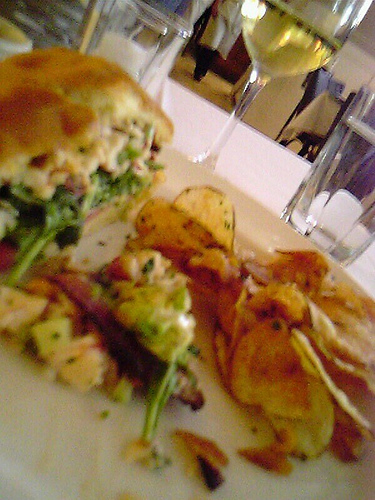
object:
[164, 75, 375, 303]
table cloth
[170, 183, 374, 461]
chips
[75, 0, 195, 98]
glass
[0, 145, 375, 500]
plate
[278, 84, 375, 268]
glass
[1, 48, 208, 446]
sandwich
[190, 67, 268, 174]
handle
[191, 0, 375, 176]
glass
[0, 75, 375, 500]
table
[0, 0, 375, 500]
food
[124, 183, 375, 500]
potato chips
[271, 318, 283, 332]
mark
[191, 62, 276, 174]
stand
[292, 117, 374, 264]
water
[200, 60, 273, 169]
stem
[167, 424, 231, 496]
piece